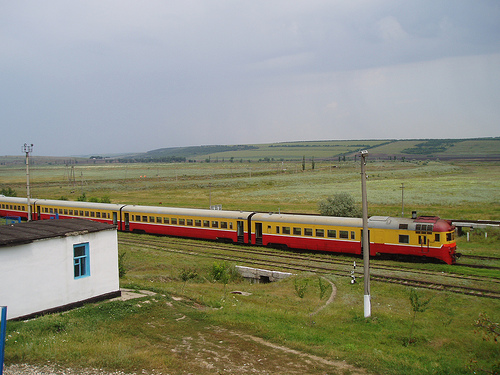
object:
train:
[0, 193, 456, 265]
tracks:
[383, 263, 483, 298]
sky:
[0, 0, 499, 156]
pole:
[358, 148, 370, 319]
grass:
[161, 239, 260, 294]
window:
[72, 241, 91, 281]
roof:
[0, 217, 117, 245]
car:
[244, 208, 355, 261]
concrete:
[395, 263, 454, 284]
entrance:
[257, 274, 274, 284]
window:
[303, 228, 312, 236]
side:
[183, 208, 248, 243]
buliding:
[13, 210, 135, 285]